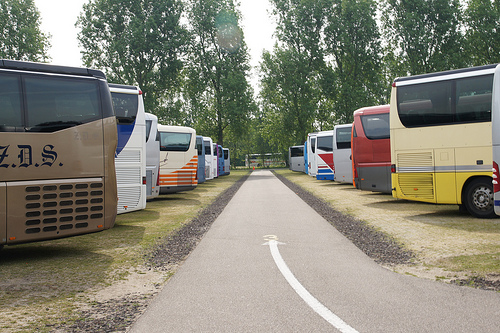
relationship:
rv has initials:
[0, 56, 120, 251] [0, 139, 62, 169]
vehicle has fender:
[349, 102, 390, 192] [347, 161, 392, 191]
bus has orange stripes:
[157, 123, 199, 194] [159, 160, 202, 184]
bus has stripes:
[314, 129, 337, 180] [316, 149, 336, 180]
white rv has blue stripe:
[110, 80, 156, 219] [114, 120, 138, 157]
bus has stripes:
[158, 122, 200, 190] [162, 157, 198, 191]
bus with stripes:
[153, 120, 200, 190] [158, 154, 200, 189]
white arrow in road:
[257, 232, 361, 331] [125, 165, 499, 330]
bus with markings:
[314, 129, 332, 179] [311, 153, 338, 185]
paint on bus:
[85, 142, 90, 162] [11, 38, 145, 275]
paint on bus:
[135, 137, 140, 151] [107, 78, 154, 213]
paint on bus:
[151, 139, 156, 149] [107, 100, 186, 212]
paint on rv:
[175, 157, 184, 162] [388, 62, 500, 221]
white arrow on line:
[258, 238, 286, 246] [267, 244, 357, 332]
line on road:
[267, 244, 357, 332] [124, 168, 499, 332]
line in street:
[267, 248, 351, 332] [235, 167, 384, 327]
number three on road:
[258, 230, 280, 246] [124, 168, 499, 332]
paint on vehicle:
[368, 142, 377, 152] [350, 102, 390, 195]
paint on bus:
[313, 162, 335, 183] [312, 127, 337, 189]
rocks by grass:
[364, 231, 384, 253] [412, 208, 497, 268]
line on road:
[267, 248, 351, 332] [124, 145, 497, 332]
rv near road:
[380, 67, 498, 221] [172, 148, 488, 330]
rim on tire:
[468, 188, 494, 208] [460, 163, 495, 217]